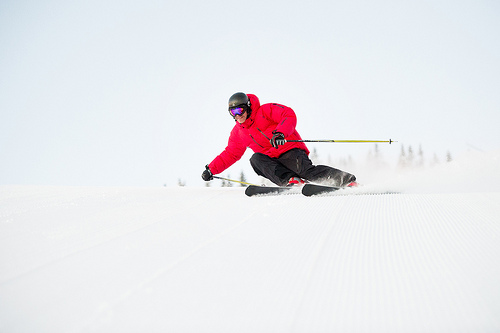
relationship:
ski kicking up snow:
[301, 181, 357, 197] [345, 150, 385, 221]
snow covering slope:
[138, 196, 308, 286] [214, 181, 373, 262]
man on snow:
[179, 64, 372, 227] [180, 179, 357, 262]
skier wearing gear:
[201, 91, 364, 197] [201, 90, 342, 201]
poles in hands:
[195, 139, 389, 187] [162, 139, 316, 175]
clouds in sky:
[124, 70, 182, 149] [80, 73, 163, 128]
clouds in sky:
[112, 59, 185, 141] [136, 46, 147, 83]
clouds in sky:
[113, 79, 149, 129] [7, 73, 68, 108]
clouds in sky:
[27, 58, 67, 104] [62, 27, 105, 64]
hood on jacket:
[242, 90, 259, 122] [226, 128, 333, 154]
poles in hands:
[277, 120, 420, 157] [177, 129, 290, 182]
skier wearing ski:
[201, 91, 355, 187] [301, 173, 355, 194]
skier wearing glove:
[201, 91, 355, 187] [199, 170, 211, 182]